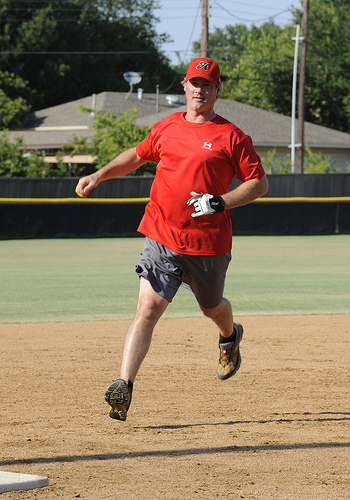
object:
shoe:
[216, 322, 243, 381]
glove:
[186, 189, 226, 218]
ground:
[0, 233, 349, 500]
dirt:
[0, 313, 349, 499]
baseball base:
[0, 469, 46, 492]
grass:
[0, 234, 350, 322]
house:
[0, 72, 350, 178]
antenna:
[122, 69, 142, 99]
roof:
[0, 91, 350, 147]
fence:
[0, 176, 350, 235]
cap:
[186, 56, 220, 86]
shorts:
[135, 235, 232, 309]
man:
[75, 57, 269, 421]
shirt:
[135, 112, 265, 256]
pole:
[200, 0, 209, 58]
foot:
[105, 377, 133, 421]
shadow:
[133, 410, 349, 429]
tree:
[0, 0, 186, 128]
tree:
[69, 103, 158, 175]